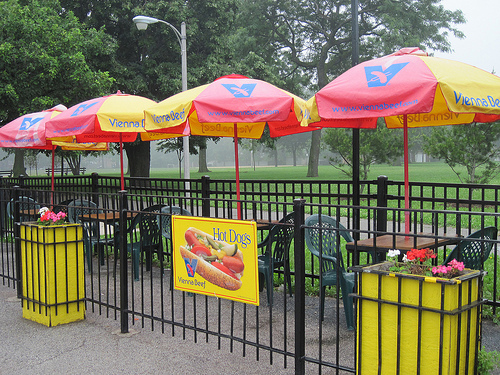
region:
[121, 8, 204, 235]
Lamp post standing next to fence.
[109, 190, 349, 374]
Wrought iron fence next to tables and chairs.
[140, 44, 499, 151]
Open red and yellow umbrellas.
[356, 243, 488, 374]
Yellow container holding flowers.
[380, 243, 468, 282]
Flowers inside yellow container.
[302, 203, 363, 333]
Chair pushed up to table.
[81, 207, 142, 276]
Table between two fences.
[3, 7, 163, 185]
Trees growing on open lawn.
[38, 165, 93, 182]
Bench sitting on lawn in background.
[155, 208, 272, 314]
Advertising sign hanging on fence.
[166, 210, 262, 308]
Hot dog advertisement on fence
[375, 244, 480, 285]
flowers in a planter beside fence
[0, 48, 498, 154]
multicolored umbrellas over tables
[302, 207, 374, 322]
green plastic chair at table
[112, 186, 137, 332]
black metal fence post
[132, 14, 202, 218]
tall street light beside seating area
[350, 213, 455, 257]
brown wooden table top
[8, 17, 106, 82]
green foliage on trees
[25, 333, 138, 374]
cracks in paved area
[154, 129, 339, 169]
fog in the background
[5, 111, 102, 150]
OPEN RED AND YELLOW UMBRELLA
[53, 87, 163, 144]
OPEN RED AND YELLOW UMBRELLA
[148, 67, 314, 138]
OPEN RED AND YELLOW UMBRELLA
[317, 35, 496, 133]
OPEN RED AND YELLOW UMBRELLA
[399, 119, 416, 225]
RED POLE ON UMBRELLA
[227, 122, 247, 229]
RED POLE ON UMBRELLA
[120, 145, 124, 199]
RED POLE ON UMBRELLA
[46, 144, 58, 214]
RED POLE ON UMBRELLA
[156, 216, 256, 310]
YELLOW SIGN ON GATE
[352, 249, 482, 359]
YELLOW FLOWER POT ON RIGHT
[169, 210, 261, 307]
hot dog advertisement sign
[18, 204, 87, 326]
yellow container of flowers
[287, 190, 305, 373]
black metal fence post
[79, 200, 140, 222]
wooden table top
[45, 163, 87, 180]
wooden slat bench in park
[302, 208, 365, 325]
green plastic chair at table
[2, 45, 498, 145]
multicolored umbrellas over tables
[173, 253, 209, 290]
Vienna Beef logo on sign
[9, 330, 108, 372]
cracks in asphalt beside fence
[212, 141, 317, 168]
fog in the background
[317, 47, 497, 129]
the umbrella is red and yellow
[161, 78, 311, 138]
the umbrella is red and yellow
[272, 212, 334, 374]
the rails are black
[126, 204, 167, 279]
the chair is blue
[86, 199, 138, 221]
the table is brown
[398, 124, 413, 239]
the pole is red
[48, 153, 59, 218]
the pole is red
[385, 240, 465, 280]
flowers are in the container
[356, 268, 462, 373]
the container is yellow